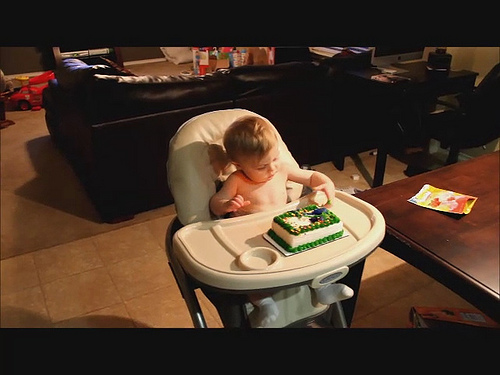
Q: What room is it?
A: It is a kitchen.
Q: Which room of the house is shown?
A: It is a kitchen.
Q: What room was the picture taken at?
A: It was taken at the kitchen.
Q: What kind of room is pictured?
A: It is a kitchen.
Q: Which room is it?
A: It is a kitchen.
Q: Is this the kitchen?
A: Yes, it is the kitchen.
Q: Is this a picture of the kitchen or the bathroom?
A: It is showing the kitchen.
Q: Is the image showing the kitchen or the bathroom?
A: It is showing the kitchen.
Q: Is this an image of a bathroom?
A: No, the picture is showing a kitchen.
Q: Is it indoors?
A: Yes, it is indoors.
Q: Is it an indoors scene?
A: Yes, it is indoors.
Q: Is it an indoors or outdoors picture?
A: It is indoors.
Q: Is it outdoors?
A: No, it is indoors.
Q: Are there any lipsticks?
A: No, there are no lipsticks.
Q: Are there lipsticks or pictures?
A: No, there are no lipsticks or pictures.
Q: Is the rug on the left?
A: Yes, the rug is on the left of the image.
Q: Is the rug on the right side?
A: No, the rug is on the left of the image.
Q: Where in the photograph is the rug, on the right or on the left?
A: The rug is on the left of the image.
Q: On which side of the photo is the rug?
A: The rug is on the left of the image.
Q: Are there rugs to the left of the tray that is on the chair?
A: Yes, there is a rug to the left of the tray.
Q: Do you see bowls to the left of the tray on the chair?
A: No, there is a rug to the left of the tray.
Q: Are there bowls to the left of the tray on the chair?
A: No, there is a rug to the left of the tray.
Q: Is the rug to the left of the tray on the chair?
A: Yes, the rug is to the left of the tray.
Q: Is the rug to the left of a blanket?
A: No, the rug is to the left of the tray.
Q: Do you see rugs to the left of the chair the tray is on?
A: Yes, there is a rug to the left of the chair.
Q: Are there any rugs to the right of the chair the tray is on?
A: No, the rug is to the left of the chair.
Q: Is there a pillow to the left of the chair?
A: No, there is a rug to the left of the chair.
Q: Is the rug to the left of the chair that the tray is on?
A: Yes, the rug is to the left of the chair.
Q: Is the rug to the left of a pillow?
A: No, the rug is to the left of the chair.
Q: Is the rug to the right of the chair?
A: No, the rug is to the left of the chair.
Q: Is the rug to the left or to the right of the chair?
A: The rug is to the left of the chair.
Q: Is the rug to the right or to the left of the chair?
A: The rug is to the left of the chair.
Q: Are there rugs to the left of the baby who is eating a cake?
A: Yes, there is a rug to the left of the baby.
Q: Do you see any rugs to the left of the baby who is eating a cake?
A: Yes, there is a rug to the left of the baby.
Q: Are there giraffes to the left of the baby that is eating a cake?
A: No, there is a rug to the left of the baby.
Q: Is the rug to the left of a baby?
A: Yes, the rug is to the left of a baby.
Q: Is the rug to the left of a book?
A: No, the rug is to the left of a baby.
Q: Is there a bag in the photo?
A: No, there are no bags.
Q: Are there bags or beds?
A: No, there are no bags or beds.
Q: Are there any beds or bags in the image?
A: No, there are no bags or beds.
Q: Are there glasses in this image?
A: No, there are no glasses.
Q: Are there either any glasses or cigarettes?
A: No, there are no glasses or cigarettes.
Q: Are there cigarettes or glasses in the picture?
A: No, there are no glasses or cigarettes.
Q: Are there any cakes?
A: Yes, there is a cake.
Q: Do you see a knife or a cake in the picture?
A: Yes, there is a cake.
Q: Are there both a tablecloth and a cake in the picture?
A: No, there is a cake but no tablecloths.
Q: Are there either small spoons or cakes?
A: Yes, there is a small cake.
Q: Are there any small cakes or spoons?
A: Yes, there is a small cake.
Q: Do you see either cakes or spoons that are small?
A: Yes, the cake is small.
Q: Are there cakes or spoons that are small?
A: Yes, the cake is small.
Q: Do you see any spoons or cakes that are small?
A: Yes, the cake is small.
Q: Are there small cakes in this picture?
A: Yes, there is a small cake.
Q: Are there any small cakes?
A: Yes, there is a small cake.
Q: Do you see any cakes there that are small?
A: Yes, there is a small cake.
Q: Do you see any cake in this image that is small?
A: Yes, there is a cake that is small.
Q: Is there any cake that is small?
A: Yes, there is a cake that is small.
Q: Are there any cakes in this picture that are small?
A: Yes, there is a cake that is small.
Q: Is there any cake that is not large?
A: Yes, there is a small cake.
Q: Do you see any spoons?
A: No, there are no spoons.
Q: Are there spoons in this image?
A: No, there are no spoons.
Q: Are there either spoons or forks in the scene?
A: No, there are no spoons or forks.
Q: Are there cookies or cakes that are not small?
A: No, there is a cake but it is small.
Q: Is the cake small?
A: Yes, the cake is small.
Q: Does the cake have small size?
A: Yes, the cake is small.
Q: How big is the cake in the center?
A: The cake is small.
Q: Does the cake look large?
A: No, the cake is small.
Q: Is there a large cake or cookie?
A: No, there is a cake but it is small.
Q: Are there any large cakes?
A: No, there is a cake but it is small.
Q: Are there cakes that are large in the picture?
A: No, there is a cake but it is small.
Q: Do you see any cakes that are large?
A: No, there is a cake but it is small.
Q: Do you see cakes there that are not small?
A: No, there is a cake but it is small.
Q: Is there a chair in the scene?
A: Yes, there is a chair.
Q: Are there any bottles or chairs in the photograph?
A: Yes, there is a chair.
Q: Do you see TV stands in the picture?
A: No, there are no TV stands.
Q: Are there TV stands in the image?
A: No, there are no TV stands.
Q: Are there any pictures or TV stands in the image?
A: No, there are no TV stands or pictures.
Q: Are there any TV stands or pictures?
A: No, there are no TV stands or pictures.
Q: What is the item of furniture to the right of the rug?
A: The piece of furniture is a chair.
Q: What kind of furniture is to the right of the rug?
A: The piece of furniture is a chair.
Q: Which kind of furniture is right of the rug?
A: The piece of furniture is a chair.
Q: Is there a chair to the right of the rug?
A: Yes, there is a chair to the right of the rug.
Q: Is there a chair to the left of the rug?
A: No, the chair is to the right of the rug.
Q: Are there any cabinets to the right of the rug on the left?
A: No, there is a chair to the right of the rug.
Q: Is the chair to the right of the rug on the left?
A: Yes, the chair is to the right of the rug.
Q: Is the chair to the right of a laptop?
A: No, the chair is to the right of the rug.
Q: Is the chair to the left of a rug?
A: No, the chair is to the right of a rug.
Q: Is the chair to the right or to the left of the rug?
A: The chair is to the right of the rug.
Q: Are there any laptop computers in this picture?
A: No, there are no laptop computers.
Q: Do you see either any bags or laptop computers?
A: No, there are no laptop computers or bags.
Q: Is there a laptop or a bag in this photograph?
A: No, there are no laptops or bags.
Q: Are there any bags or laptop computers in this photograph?
A: No, there are no laptop computers or bags.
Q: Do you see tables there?
A: Yes, there is a table.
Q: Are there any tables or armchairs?
A: Yes, there is a table.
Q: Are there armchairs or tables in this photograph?
A: Yes, there is a table.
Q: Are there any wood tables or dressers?
A: Yes, there is a wood table.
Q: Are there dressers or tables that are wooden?
A: Yes, the table is wooden.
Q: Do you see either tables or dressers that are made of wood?
A: Yes, the table is made of wood.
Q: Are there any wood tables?
A: Yes, there is a wood table.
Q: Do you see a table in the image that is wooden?
A: Yes, there is a table that is wooden.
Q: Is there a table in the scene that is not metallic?
A: Yes, there is a wooden table.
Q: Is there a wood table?
A: Yes, there is a table that is made of wood.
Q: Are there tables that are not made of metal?
A: Yes, there is a table that is made of wood.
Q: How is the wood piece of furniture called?
A: The piece of furniture is a table.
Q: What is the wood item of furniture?
A: The piece of furniture is a table.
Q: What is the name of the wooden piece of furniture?
A: The piece of furniture is a table.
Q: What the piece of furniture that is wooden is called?
A: The piece of furniture is a table.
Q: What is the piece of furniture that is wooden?
A: The piece of furniture is a table.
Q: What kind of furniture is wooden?
A: The furniture is a table.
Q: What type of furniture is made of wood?
A: The furniture is a table.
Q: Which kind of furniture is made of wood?
A: The furniture is a table.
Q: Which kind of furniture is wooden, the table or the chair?
A: The table is wooden.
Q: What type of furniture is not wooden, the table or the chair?
A: The chair is not wooden.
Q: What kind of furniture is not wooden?
A: The furniture is a chair.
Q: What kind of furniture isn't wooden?
A: The furniture is a chair.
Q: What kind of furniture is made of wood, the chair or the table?
A: The table is made of wood.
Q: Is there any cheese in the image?
A: No, there is no cheese.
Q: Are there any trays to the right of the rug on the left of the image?
A: Yes, there is a tray to the right of the rug.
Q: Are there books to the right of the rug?
A: No, there is a tray to the right of the rug.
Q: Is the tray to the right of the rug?
A: Yes, the tray is to the right of the rug.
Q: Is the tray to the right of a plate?
A: No, the tray is to the right of the rug.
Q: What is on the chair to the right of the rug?
A: The tray is on the chair.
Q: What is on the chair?
A: The tray is on the chair.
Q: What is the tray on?
A: The tray is on the chair.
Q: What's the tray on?
A: The tray is on the chair.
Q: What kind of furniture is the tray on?
A: The tray is on the chair.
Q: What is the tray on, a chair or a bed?
A: The tray is on a chair.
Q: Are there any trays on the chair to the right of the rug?
A: Yes, there is a tray on the chair.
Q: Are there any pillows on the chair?
A: No, there is a tray on the chair.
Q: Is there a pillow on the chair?
A: No, there is a tray on the chair.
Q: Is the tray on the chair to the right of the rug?
A: Yes, the tray is on the chair.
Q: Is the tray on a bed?
A: No, the tray is on the chair.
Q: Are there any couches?
A: Yes, there is a couch.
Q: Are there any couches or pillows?
A: Yes, there is a couch.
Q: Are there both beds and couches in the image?
A: No, there is a couch but no beds.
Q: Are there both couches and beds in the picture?
A: No, there is a couch but no beds.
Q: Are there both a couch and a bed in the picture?
A: No, there is a couch but no beds.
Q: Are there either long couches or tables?
A: Yes, there is a long couch.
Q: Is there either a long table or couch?
A: Yes, there is a long couch.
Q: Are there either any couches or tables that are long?
A: Yes, the couch is long.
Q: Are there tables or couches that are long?
A: Yes, the couch is long.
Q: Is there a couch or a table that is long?
A: Yes, the couch is long.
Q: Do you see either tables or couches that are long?
A: Yes, the couch is long.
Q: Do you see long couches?
A: Yes, there is a long couch.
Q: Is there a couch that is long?
A: Yes, there is a couch that is long.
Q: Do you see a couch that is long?
A: Yes, there is a couch that is long.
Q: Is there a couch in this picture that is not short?
A: Yes, there is a long couch.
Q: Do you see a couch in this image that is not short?
A: Yes, there is a long couch.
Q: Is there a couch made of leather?
A: Yes, there is a couch that is made of leather.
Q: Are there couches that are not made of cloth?
A: Yes, there is a couch that is made of leather.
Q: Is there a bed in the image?
A: No, there are no beds.